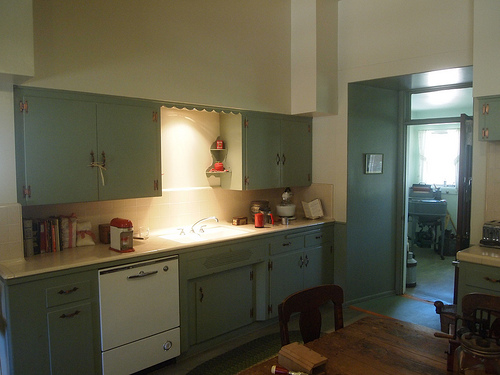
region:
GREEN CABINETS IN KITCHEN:
[183, 221, 364, 358]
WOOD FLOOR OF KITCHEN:
[272, 305, 390, 366]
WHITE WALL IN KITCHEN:
[81, 21, 346, 148]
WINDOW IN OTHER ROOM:
[403, 115, 469, 176]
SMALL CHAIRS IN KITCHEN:
[443, 268, 494, 373]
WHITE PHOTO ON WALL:
[358, 147, 395, 177]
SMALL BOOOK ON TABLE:
[266, 337, 314, 367]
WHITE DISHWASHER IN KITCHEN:
[94, 278, 220, 362]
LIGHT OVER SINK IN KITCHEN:
[152, 100, 244, 175]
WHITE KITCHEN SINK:
[145, 200, 262, 256]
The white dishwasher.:
[97, 262, 180, 372]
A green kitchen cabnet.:
[23, 100, 100, 202]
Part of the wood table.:
[353, 343, 408, 366]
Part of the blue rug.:
[227, 353, 255, 365]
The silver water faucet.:
[193, 215, 222, 227]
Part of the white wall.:
[202, 84, 289, 99]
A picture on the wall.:
[363, 151, 384, 174]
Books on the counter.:
[23, 215, 73, 255]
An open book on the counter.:
[301, 198, 326, 220]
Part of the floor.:
[383, 300, 432, 312]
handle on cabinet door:
[98, 151, 115, 171]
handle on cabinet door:
[86, 152, 96, 170]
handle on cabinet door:
[271, 151, 283, 166]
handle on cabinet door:
[281, 153, 288, 170]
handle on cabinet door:
[296, 255, 306, 269]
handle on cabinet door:
[303, 255, 318, 269]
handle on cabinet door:
[196, 285, 207, 303]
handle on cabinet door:
[61, 309, 81, 322]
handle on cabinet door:
[51, 280, 81, 297]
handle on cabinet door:
[475, 272, 497, 287]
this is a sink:
[153, 216, 251, 246]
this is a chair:
[428, 282, 498, 372]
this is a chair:
[249, 272, 352, 355]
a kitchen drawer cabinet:
[39, 278, 103, 305]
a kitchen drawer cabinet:
[43, 298, 103, 374]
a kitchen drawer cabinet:
[90, 257, 203, 374]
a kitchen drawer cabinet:
[174, 263, 282, 340]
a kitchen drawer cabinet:
[273, 249, 329, 316]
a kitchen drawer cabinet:
[273, 220, 340, 247]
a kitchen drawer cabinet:
[19, 93, 100, 206]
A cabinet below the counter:
[46, 287, 88, 304]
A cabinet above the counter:
[240, 115, 310, 192]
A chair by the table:
[273, 280, 345, 342]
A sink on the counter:
[176, 215, 247, 242]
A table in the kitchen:
[252, 315, 486, 374]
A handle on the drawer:
[56, 283, 79, 296]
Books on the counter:
[23, 215, 78, 252]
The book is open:
[299, 198, 324, 220]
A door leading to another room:
[449, 115, 479, 309]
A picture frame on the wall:
[363, 153, 386, 173]